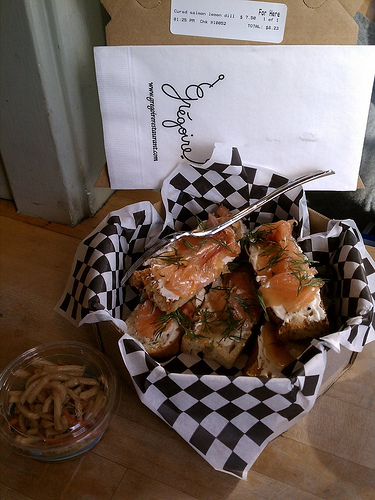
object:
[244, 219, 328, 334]
sandwich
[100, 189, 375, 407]
basket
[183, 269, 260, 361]
sandwich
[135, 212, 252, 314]
sandwich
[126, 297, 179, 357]
sandwich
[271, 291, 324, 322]
cream cheese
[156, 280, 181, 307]
cream cheese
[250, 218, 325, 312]
fish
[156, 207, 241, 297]
fish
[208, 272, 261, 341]
fish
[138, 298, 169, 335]
fish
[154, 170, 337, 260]
spoon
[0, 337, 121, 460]
cup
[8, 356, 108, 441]
salad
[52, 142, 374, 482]
napkin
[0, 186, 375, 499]
floor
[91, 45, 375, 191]
paper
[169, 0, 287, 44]
label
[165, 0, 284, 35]
letters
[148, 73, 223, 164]
type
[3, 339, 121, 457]
lid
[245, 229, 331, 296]
dill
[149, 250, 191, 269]
dill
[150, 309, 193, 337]
dill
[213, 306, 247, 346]
dill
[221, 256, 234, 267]
cream cheese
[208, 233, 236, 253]
dill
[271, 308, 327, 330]
toast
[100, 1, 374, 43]
box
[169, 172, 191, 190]
checks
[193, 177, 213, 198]
checks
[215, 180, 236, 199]
checks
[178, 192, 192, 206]
checks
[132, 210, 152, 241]
checks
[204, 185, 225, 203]
checks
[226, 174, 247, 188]
checks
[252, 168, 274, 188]
checks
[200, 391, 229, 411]
checks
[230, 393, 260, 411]
checks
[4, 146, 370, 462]
meal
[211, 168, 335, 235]
handle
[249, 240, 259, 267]
cream cheese